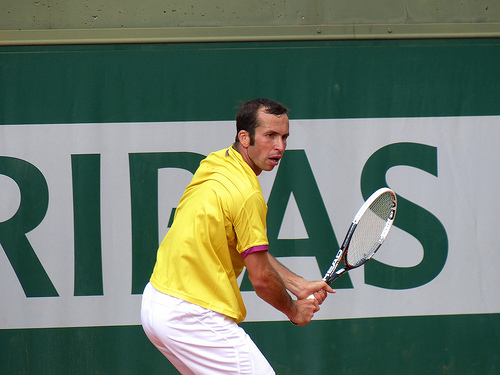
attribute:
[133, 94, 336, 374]
man — focused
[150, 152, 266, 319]
t-shirt — yellow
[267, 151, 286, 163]
mouth — open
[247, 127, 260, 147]
sideburn — long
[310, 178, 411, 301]
racket — black, white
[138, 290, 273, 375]
pants — white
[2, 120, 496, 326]
sign — green, white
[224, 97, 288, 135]
hair — short, black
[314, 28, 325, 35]
bolt — beige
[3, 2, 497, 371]
wall — beige